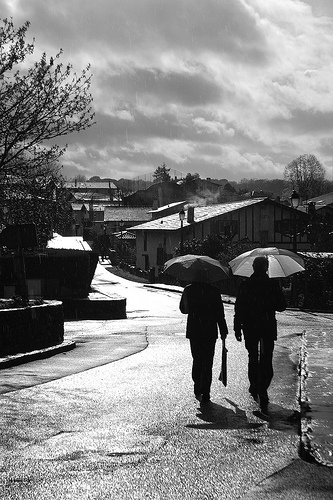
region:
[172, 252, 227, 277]
THIS IS AN UMBRELLA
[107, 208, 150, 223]
THIS IS A HOUSE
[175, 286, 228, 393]
THIS IS A PERSON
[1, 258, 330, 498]
wet, shiny street on a town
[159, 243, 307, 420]
couple of people walking down street with umbrellas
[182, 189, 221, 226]
smoke coming from a house's chimney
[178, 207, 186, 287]
street lights near the sidewalk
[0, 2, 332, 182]
cloudy, gray sky with a touch of sun on th right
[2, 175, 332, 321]
buildings in the town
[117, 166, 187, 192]
suspension bridge in a distance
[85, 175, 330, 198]
hills in the distance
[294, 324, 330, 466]
part of sidewalk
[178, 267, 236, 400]
this is a person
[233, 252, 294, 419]
this is a person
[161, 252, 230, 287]
this is an umbrella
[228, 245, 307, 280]
this is an umbrella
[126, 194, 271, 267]
this is a building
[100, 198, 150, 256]
this is a building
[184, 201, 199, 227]
this is a chimney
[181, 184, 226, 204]
this is a cloud of smoke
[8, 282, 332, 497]
this is the road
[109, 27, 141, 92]
white clouds in blue sky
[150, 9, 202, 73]
white clouds in blue sky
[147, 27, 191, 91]
white clouds in blue sky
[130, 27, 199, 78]
white clouds in blue sky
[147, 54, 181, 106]
white clouds in blue sky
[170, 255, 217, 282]
open umbrella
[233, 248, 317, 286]
open umbrella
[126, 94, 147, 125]
white clouds in blue sky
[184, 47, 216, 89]
white clouds in blue sky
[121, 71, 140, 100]
white clouds in blue sky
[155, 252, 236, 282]
open umbrella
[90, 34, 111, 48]
white clouds in blue sky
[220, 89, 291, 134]
white clouds in blue sky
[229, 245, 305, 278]
the umbrella is opened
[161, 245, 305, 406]
the people carrying the umbrellas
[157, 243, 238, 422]
person holding an umbrella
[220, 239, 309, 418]
person holding an umbrella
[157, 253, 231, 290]
the umbrella is black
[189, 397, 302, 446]
shadows on the ground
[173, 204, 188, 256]
a street light on a pole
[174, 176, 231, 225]
smoke exit from a chiminey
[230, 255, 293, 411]
man wears black clothes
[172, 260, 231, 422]
woman wears black clothes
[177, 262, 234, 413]
person carry a bag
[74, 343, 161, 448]
sun light on the road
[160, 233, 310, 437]
a pair of people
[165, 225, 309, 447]
the people are walking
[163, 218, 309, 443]
people are holding umbrella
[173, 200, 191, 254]
light on a pole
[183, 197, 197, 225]
chimney on a roof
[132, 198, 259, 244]
roof of the house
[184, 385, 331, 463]
shadows on the ground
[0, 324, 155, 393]
patch on the pavement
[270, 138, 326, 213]
a tree in the distance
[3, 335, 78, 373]
curb next to the road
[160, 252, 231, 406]
person holding black umbrella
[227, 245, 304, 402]
person holding black umbrella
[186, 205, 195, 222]
chimney on top of building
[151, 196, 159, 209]
chimney on top of building